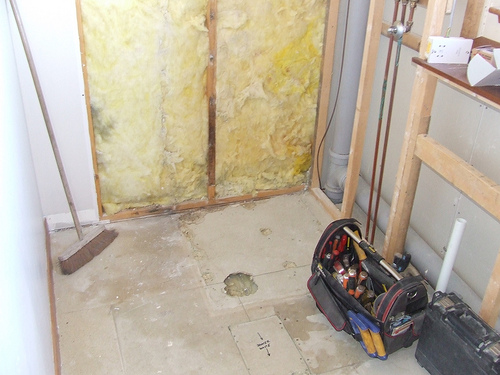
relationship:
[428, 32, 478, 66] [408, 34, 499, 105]
outlet on shelf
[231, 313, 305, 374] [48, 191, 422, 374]
tile on floor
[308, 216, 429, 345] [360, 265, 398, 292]
box with tool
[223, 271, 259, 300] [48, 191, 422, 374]
drain in floor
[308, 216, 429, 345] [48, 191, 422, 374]
box on floor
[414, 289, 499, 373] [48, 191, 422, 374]
case on floor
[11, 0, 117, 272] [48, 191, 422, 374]
broom on floor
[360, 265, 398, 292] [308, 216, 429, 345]
tool in box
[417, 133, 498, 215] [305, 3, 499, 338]
wood on wall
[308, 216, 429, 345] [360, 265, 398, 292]
box filled with tool